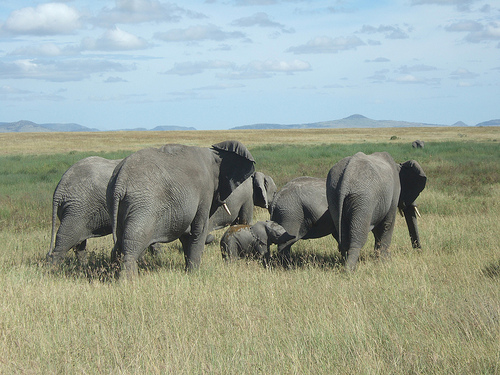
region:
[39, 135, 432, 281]
a herd of elephants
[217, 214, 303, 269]
a baby elephant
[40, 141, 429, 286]
elephants surrounding a baby elephant as they walk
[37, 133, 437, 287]
elephants walking on a grassy plain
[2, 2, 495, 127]
blue sky with puffy clouds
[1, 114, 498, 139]
mountains far in the distance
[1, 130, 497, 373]
a grassy savanah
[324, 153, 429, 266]
an elephant walking in a herd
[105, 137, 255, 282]
an elephant walking in a herd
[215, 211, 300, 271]
a baby elephant walking in a herd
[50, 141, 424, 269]
Elephants in a field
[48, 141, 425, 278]
The elephants are gray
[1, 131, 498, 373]
A large field of grass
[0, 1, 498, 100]
Clouds are in the sky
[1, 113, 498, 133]
Mountains in the distance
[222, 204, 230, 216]
Tusk is sticking out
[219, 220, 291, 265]
Elephant is a baby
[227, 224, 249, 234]
Baby has dirt on back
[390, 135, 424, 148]
Two elephants in distance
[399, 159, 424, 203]
Ear sticking out to the right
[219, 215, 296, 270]
a baby elephant in tall grass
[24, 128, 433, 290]
the baby elephant is surrounded by adults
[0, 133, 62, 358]
the terrain is green and yellow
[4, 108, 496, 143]
mountains appear to be in the distance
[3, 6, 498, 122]
the sky is cloudy with a haze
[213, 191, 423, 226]
you can see three elephant tusks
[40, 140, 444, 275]
the elephants are a gray color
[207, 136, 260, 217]
elephant ears are very large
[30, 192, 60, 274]
elephant tails and long and thin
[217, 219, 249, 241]
the baby elephant has a brown color on its back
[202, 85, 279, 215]
the ear of a elephant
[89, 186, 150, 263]
the tail of a elephant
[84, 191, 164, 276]
the back leg of a elephant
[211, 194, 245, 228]
the tusk of a elephant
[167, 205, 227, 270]
the front leg of a elephant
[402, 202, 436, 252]
the trunk of a elephant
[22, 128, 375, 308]
elephants in a field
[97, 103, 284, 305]
a elephant standing on grass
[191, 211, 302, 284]
a grey baby elephant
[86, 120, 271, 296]
a big grey elephant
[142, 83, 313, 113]
Sky is blue color.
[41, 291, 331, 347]
Grass is brown color.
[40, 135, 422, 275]
Elephants are walking in grass.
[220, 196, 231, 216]
Tusk are white color.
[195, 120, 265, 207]
Elephant has big ears.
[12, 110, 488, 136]
Hills are at far distance.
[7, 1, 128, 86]
Clouds are white color.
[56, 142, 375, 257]
Elephant is grey color.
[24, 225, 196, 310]
Shadow falls on grass.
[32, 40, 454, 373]
Day time picture.